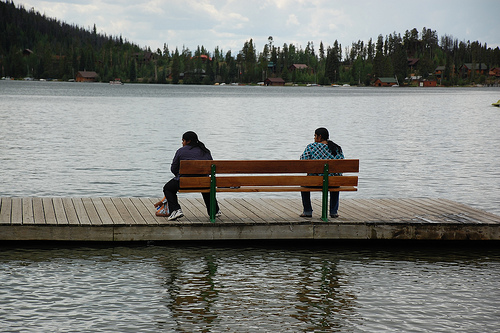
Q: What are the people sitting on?
A: Bench.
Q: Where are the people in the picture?
A: On the bench.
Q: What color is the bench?
A: Brown.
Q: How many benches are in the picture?
A: One.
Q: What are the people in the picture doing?
A: Sitting.